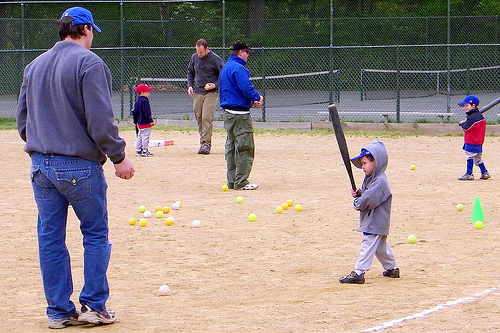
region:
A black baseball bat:
[323, 104, 367, 196]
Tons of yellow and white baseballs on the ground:
[126, 161, 486, 294]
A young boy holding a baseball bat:
[321, 102, 414, 283]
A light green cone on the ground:
[468, 195, 488, 224]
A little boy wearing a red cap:
[131, 80, 161, 157]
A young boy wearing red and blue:
[456, 95, 490, 180]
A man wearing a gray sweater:
[186, 39, 224, 153]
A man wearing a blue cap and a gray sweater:
[16, 6, 134, 327]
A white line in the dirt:
[349, 278, 499, 331]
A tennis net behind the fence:
[123, 67, 349, 109]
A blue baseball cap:
[57, 6, 99, 31]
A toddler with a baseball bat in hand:
[134, 83, 151, 155]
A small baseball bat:
[327, 103, 358, 195]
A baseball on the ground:
[455, 203, 463, 210]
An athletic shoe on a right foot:
[78, 302, 113, 324]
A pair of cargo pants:
[222, 111, 254, 188]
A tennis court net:
[360, 64, 499, 100]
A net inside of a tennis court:
[360, 68, 499, 99]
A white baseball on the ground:
[157, 284, 167, 294]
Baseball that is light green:
[407, 233, 418, 245]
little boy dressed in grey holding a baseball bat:
[337, 137, 402, 282]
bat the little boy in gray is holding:
[326, 102, 360, 194]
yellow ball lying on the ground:
[404, 229, 416, 245]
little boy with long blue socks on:
[453, 88, 492, 183]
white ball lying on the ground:
[190, 217, 202, 231]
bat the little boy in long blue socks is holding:
[474, 90, 499, 112]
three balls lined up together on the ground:
[272, 195, 294, 213]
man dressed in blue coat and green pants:
[215, 37, 260, 192]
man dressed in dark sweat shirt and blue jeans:
[14, 2, 144, 329]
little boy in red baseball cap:
[126, 75, 157, 159]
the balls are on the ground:
[132, 187, 315, 242]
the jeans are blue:
[23, 155, 133, 295]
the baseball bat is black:
[320, 99, 368, 209]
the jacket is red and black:
[450, 114, 493, 155]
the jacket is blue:
[215, 59, 265, 109]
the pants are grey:
[215, 111, 262, 180]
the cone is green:
[462, 191, 491, 236]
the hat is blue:
[350, 143, 370, 169]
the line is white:
[402, 282, 485, 332]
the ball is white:
[186, 214, 210, 236]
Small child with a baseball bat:
[327, 101, 403, 283]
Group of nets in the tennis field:
[129, 66, 499, 120]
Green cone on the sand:
[468, 193, 486, 226]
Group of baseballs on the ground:
[128, 185, 305, 227]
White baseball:
[158, 284, 173, 297]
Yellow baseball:
[474, 219, 484, 229]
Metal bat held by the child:
[326, 103, 358, 208]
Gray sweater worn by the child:
[354, 143, 394, 237]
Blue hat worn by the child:
[456, 95, 479, 107]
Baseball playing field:
[0, 127, 499, 327]